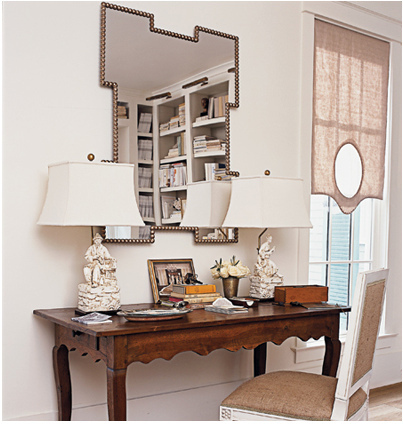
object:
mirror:
[96, 1, 239, 247]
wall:
[1, 2, 308, 424]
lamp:
[39, 159, 146, 313]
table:
[34, 303, 353, 423]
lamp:
[221, 175, 315, 306]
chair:
[221, 270, 390, 421]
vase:
[211, 255, 247, 301]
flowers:
[208, 254, 221, 278]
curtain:
[310, 17, 389, 215]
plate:
[120, 306, 183, 322]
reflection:
[121, 75, 227, 244]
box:
[273, 284, 328, 306]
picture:
[145, 257, 196, 304]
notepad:
[72, 309, 114, 324]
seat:
[223, 368, 368, 417]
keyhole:
[333, 138, 363, 203]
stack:
[171, 282, 214, 307]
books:
[169, 283, 217, 295]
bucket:
[222, 275, 241, 296]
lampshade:
[38, 158, 144, 228]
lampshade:
[218, 176, 315, 231]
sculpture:
[72, 231, 125, 320]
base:
[79, 231, 121, 311]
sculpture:
[248, 231, 283, 299]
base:
[248, 233, 285, 300]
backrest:
[333, 262, 388, 407]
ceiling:
[358, 1, 402, 29]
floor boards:
[0, 342, 402, 424]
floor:
[374, 388, 397, 421]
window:
[305, 11, 388, 351]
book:
[207, 297, 250, 317]